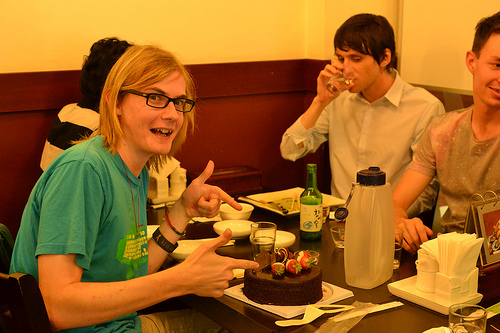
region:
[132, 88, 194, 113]
The eyeglasses the person on the left is wearing.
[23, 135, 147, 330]
The green shirt the person on the left is wearing.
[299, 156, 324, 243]
The green glass bottle on the table.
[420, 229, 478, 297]
The napkins in the holder on the table.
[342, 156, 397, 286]
The plastic container on the table.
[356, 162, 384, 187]
The black cap of the container on the table.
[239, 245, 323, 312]
The cake on the plate.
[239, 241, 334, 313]
A cake on the table.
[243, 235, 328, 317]
Strawberries on top of the cake.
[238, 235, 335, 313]
The cake has chocolate frosting.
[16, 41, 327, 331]
A person in a blue shirt points at the cake.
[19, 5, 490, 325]
A group of people gather around a table.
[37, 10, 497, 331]
A group of people are dining.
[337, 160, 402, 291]
A plastic container on the table.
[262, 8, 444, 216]
A man is drinking from a glass.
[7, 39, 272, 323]
The person with blond hair is wearing glasses.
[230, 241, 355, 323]
The cake has not been cut yet.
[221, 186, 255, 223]
white dish on table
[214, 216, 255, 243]
white dish on table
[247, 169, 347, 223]
white dish on table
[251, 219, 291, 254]
white dish on table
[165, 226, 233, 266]
white dish on table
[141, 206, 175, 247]
white dish on table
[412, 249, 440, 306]
white dish on table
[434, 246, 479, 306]
white dish on table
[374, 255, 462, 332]
white dish on table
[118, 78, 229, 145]
the glasses are black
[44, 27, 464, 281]
this is a group of people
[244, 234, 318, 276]
this is a dessert cake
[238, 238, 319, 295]
the cake is whole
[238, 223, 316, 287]
the cake is chocolate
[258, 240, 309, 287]
the cake is brown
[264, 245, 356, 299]
the strawberries are red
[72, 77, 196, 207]
the girl is blonde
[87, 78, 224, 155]
the glasses are black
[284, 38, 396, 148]
the man is drinking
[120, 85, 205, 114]
a woman wearing glasses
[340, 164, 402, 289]
a plastic container with a black lid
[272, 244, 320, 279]
strawberries on a cake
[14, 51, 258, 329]
woman pointing at a cake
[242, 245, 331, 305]
chocolate cake with strawberries on top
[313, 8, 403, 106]
man drinking from a glass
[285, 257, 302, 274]
white chocolate covered strawberry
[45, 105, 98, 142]
black and white striped shirt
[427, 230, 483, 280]
stack of white napkins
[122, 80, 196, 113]
black glasses on woman's face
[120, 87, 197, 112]
the glasses are black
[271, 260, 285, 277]
the strawberry is red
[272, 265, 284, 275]
the stem is green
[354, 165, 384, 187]
the cover is black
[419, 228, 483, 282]
the napkins are white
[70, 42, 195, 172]
the hair is blonde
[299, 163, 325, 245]
the bottle is green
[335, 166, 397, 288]
the plastic bottle has a black cover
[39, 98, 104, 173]
the shirt is striped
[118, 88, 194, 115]
The glasses are black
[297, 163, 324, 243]
The bottle is green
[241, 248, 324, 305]
The cake has strawberries on it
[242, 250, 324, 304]
the cake is brown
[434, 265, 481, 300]
The napkin holder is white